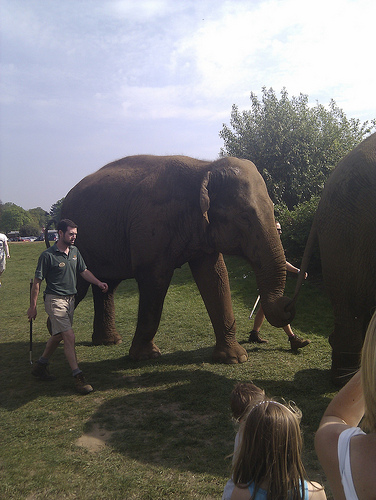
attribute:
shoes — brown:
[28, 353, 94, 393]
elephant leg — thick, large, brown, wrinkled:
[187, 251, 248, 363]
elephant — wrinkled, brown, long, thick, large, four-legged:
[42, 152, 292, 363]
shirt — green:
[34, 240, 87, 296]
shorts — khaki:
[38, 287, 85, 336]